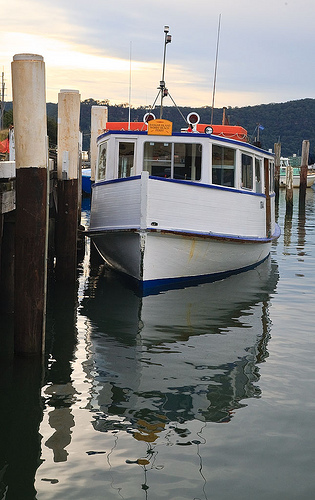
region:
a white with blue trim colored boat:
[93, 124, 289, 293]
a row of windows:
[95, 135, 268, 191]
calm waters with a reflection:
[68, 265, 302, 448]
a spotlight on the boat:
[203, 123, 219, 139]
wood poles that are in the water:
[8, 48, 61, 383]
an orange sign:
[144, 116, 175, 141]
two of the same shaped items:
[138, 106, 204, 133]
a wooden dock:
[3, 156, 99, 230]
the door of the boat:
[253, 151, 279, 240]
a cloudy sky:
[0, 2, 303, 100]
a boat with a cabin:
[63, 89, 285, 300]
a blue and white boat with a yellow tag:
[42, 117, 297, 288]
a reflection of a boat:
[67, 243, 293, 463]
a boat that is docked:
[52, 10, 289, 300]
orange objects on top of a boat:
[88, 94, 313, 189]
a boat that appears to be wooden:
[70, 117, 287, 306]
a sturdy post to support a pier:
[55, 83, 83, 272]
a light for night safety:
[123, 16, 203, 160]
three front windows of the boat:
[113, 137, 203, 190]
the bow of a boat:
[105, 134, 206, 301]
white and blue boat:
[86, 129, 281, 286]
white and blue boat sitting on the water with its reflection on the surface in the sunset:
[1, 0, 314, 499]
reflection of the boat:
[81, 255, 274, 438]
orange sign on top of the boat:
[146, 117, 172, 134]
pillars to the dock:
[11, 51, 99, 296]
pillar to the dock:
[300, 137, 309, 191]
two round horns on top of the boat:
[143, 111, 200, 134]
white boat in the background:
[277, 157, 313, 188]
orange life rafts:
[105, 120, 246, 144]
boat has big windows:
[141, 140, 201, 180]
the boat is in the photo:
[6, 31, 306, 490]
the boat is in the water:
[63, 108, 310, 324]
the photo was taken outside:
[2, 5, 296, 498]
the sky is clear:
[16, 10, 310, 73]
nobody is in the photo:
[0, 0, 312, 496]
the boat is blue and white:
[90, 146, 295, 304]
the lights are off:
[141, 99, 239, 153]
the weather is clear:
[6, 5, 313, 496]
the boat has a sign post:
[135, 112, 196, 152]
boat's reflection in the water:
[81, 266, 281, 479]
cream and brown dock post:
[9, 50, 52, 354]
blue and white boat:
[97, 125, 278, 289]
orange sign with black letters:
[147, 116, 174, 139]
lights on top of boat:
[136, 22, 196, 125]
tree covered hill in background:
[3, 93, 313, 151]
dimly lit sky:
[3, 4, 305, 104]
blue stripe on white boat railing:
[151, 171, 271, 201]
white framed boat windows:
[98, 137, 270, 189]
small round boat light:
[199, 121, 216, 137]